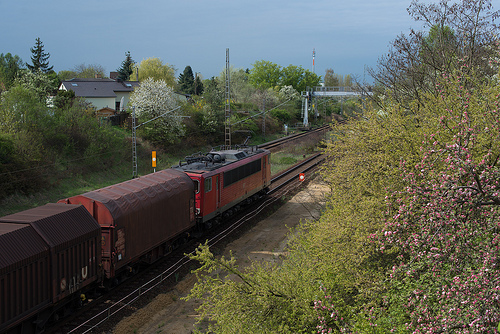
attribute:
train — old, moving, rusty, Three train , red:
[3, 103, 273, 325]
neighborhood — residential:
[40, 80, 198, 134]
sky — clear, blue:
[1, 0, 499, 89]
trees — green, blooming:
[1, 30, 357, 159]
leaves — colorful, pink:
[300, 52, 500, 331]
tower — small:
[310, 46, 320, 73]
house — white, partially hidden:
[60, 78, 133, 112]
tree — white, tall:
[127, 69, 185, 130]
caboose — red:
[175, 149, 273, 225]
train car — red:
[60, 166, 195, 284]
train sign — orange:
[147, 146, 159, 173]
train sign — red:
[297, 170, 307, 186]